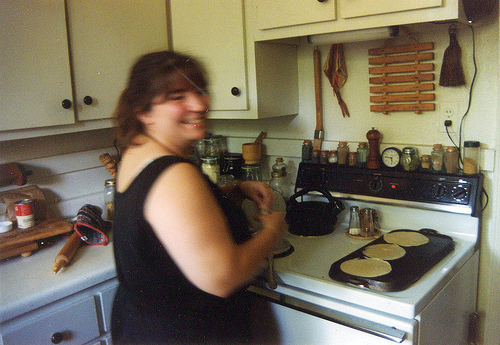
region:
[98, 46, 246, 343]
Woman wearing all black.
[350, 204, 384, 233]
The salt and pepper shaker.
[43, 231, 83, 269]
The wooden rolling pin.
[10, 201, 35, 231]
Red and white can of soup.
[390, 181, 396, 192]
Power light on the stove.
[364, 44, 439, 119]
Wooden hanging grater on the wall.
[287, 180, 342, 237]
Black tea kettle.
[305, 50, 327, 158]
Wooden hanging brush.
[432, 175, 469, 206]
Two knobs on the stove.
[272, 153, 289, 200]
The glass jar.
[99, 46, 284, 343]
Woman standing by oven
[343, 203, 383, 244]
Salt and pepper shakers on stovetop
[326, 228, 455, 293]
Pancakes on a black griddle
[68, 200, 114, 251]
Black and red oven mitt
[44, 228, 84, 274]
Light brown rolling pin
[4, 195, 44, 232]
Red and white soup can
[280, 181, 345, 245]
Black tea kettle on stovetop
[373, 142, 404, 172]
Kitchen timer on top of oven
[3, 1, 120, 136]
White kitchen cupboards with black knobs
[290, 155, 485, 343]
Black and white oven in kitchen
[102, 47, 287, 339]
a brown haired woman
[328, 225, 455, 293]
a griddle with 3 pancakes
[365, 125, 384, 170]
a wooden pepper grinder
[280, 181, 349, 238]
a black coffee kettle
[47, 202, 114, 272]
a wooden rolling pin and oven mitt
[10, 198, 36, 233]
a can of Campbell's soup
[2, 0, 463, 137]
a set of white kitchen cabinets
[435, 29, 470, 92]
a dark whisk broom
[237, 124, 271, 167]
a mortar and pestle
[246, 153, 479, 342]
a white kitchen stove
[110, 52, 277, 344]
large woman wearing black dress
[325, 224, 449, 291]
round food cooking on hot plate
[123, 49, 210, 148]
woman is smiling at camera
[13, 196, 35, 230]
can of soup on coutner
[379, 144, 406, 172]
analog clock on top of stove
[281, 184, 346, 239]
black tea pot on range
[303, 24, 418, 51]
neon light is turned off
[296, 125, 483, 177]
spices and herbs lined up on top of range control panel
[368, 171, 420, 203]
red light on range is turned on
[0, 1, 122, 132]
white cabinet with black handles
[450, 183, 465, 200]
a black oven knob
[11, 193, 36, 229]
a small soup can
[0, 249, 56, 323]
part of a counter top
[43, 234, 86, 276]
a long brown rolling pin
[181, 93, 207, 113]
the nose of a woman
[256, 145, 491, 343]
part of a black and white oven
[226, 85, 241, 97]
a black cabinet knob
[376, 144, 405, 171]
a small clock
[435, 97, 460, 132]
a white wall outlet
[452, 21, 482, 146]
a long black cord